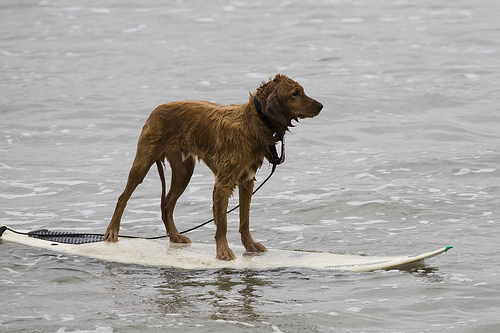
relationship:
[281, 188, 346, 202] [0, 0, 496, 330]
foam in water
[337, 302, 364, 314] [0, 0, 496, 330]
foam in water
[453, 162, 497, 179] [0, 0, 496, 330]
foam in water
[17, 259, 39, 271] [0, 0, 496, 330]
foam in water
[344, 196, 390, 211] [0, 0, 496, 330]
foam in water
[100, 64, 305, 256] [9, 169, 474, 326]
dog on surfboard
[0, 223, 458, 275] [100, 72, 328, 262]
board connected to dog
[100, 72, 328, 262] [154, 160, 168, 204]
dog has tail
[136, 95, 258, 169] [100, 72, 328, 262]
torso of a dog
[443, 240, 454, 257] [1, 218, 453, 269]
tip of a surfboard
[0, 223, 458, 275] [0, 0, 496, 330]
board in water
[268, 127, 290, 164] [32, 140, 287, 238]
clip on part of a leash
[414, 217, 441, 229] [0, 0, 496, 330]
foam in water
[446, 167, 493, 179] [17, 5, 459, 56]
foam in water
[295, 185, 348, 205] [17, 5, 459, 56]
foam in water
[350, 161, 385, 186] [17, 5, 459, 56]
foam in water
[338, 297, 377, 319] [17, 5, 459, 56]
foam in water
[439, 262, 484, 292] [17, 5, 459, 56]
foam in water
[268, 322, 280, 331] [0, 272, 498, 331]
foam in water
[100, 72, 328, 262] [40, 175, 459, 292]
dog on surfboard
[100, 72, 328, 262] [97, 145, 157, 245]
dog has leg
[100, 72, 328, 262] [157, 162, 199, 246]
dog has leg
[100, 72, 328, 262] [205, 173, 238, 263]
dog has leg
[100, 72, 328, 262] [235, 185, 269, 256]
dog has leg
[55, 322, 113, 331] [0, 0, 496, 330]
foam in water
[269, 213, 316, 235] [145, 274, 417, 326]
foam in water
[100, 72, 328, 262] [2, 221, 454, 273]
dog on surfboard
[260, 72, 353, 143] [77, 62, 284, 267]
head of dog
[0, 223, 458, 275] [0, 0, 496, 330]
board on water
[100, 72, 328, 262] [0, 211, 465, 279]
dog on board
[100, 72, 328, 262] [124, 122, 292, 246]
dog on leash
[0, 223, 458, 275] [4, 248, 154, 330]
board in water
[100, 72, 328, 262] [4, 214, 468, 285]
dog looking out from surfboard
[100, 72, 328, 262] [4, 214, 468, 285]
dog on surfboard